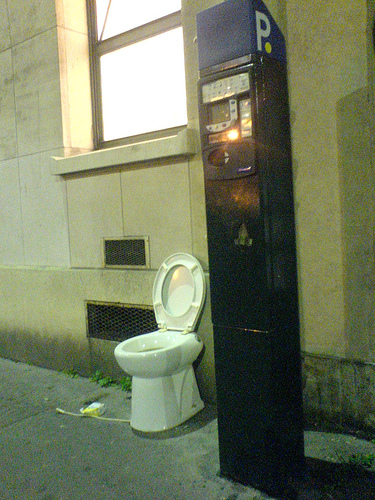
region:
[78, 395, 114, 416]
box of cigarettes on the ground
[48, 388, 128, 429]
box of cigarettes on the ground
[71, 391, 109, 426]
box of cigarettes on the ground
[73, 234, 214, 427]
Toilet on the street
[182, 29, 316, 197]
Parking meter ticket machine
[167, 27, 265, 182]
Computer machine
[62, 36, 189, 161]
window on the side of building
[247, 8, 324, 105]
P for parking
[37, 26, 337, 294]
Cement building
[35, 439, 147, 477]
Cement sidewalk along the building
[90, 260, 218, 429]
Broken toilet on the sidewalk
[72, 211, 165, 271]
Air vents on the side of the building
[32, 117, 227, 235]
Window sill on the cement building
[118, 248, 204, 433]
White porcelain toilet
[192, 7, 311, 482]
Public parking fee station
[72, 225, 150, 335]
Outside vents on building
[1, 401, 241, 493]
Cement sidewalk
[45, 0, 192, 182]
Buildings window with lights on inside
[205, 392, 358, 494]
Shadow on cement side walk from parking fee station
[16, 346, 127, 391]
Weeds growing on the side of the building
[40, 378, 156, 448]
Garbage on the sidewalk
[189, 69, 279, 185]
Payment options of parking fee structure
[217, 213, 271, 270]
Ticket drop area on parking fee structure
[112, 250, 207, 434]
a tall white toliet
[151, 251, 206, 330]
a plastic toilet lid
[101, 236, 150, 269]
a small open vent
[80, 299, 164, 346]
black and white vent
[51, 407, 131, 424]
a narrow white hose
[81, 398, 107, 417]
yellow and white pack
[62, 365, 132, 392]
a line of small green weeds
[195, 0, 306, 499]
a black and blue meter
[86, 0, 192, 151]
a clear metal window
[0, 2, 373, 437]
gray and white wall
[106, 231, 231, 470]
Broken toilet on the street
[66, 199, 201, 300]
Air vents on the wall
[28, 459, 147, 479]
Cement sidewalks along the building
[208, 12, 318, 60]
Parking sign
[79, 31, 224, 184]
Window on the side of the building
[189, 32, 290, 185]
Parking meter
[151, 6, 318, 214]
Street parking meter for tickets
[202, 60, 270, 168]
Accepts credit cards for parking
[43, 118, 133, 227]
Cement building